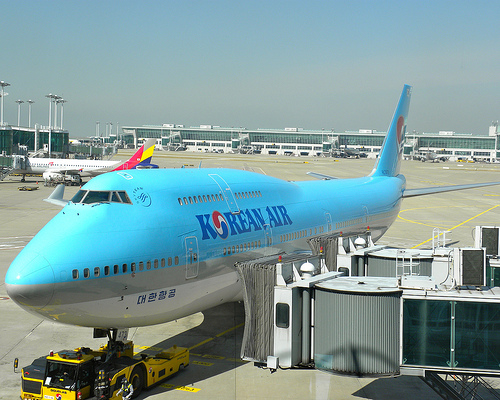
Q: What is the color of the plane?
A: Blue and white.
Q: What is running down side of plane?
A: Windows.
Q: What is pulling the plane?
A: A tractor.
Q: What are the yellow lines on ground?
A: Airport ground markings.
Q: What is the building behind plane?
A: Airport.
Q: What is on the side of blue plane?
A: A silver or white airplane.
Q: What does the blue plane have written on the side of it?
A: Korean Air.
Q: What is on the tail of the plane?
A: A red logo.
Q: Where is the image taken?
A: In runway.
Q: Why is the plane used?
A: To travel.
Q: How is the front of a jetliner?
A: Sharp.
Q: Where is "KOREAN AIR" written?
A: On side of a plane.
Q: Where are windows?
A: On side of the plane.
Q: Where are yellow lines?
A: On the tarmac.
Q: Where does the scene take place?
A: At an airport.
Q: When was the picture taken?
A: During the daytime.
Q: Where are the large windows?
A: On front of the plane.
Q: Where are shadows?
A: On the ground.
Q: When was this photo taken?
A: During the day.